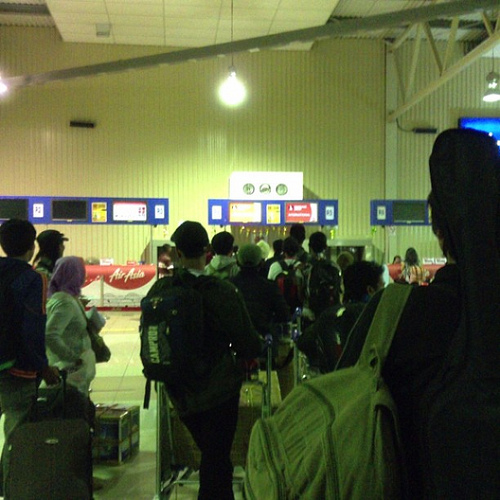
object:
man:
[139, 218, 267, 499]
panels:
[207, 199, 339, 227]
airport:
[1, 0, 498, 498]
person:
[224, 242, 299, 399]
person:
[46, 254, 95, 401]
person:
[293, 260, 387, 372]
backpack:
[242, 279, 418, 499]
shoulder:
[332, 267, 485, 366]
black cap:
[170, 220, 210, 248]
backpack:
[139, 276, 228, 404]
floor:
[85, 311, 174, 426]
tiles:
[108, 348, 137, 399]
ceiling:
[0, 0, 500, 52]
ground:
[350, 180, 410, 240]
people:
[0, 128, 500, 500]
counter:
[75, 260, 152, 310]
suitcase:
[1, 373, 99, 500]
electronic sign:
[1, 194, 168, 226]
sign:
[78, 262, 158, 314]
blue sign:
[207, 199, 337, 227]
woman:
[38, 249, 104, 401]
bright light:
[218, 75, 248, 111]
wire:
[228, 0, 235, 75]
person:
[386, 253, 403, 282]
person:
[399, 244, 423, 281]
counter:
[387, 263, 444, 282]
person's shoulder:
[333, 283, 434, 368]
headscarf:
[46, 256, 86, 299]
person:
[334, 126, 499, 496]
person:
[269, 243, 310, 318]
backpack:
[273, 257, 305, 310]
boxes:
[89, 400, 140, 465]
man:
[0, 215, 60, 454]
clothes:
[139, 267, 266, 497]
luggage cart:
[152, 320, 275, 496]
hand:
[68, 355, 84, 366]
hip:
[43, 354, 79, 382]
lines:
[0, 0, 500, 261]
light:
[213, 72, 249, 109]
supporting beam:
[0, 0, 500, 109]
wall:
[6, 19, 493, 335]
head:
[49, 256, 87, 292]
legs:
[168, 384, 243, 500]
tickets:
[206, 199, 339, 228]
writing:
[148, 323, 160, 364]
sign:
[203, 198, 339, 227]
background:
[208, 201, 342, 225]